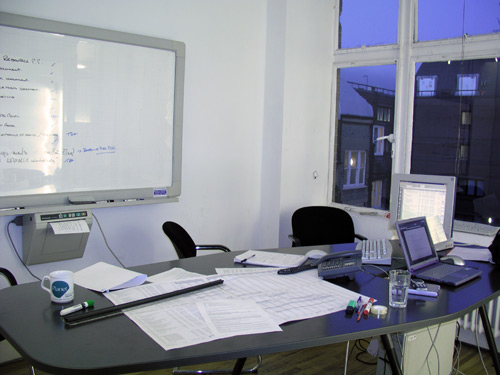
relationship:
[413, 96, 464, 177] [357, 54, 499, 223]
wall on building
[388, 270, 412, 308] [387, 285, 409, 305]
glass filled with water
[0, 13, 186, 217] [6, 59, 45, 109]
board with writing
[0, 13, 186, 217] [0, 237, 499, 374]
board behind table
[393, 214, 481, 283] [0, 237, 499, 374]
laptop on top of table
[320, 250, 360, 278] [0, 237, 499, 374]
telephone on top of table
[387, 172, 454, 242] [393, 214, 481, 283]
monitor behind laptop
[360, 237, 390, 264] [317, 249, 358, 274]
keyboard behind telephone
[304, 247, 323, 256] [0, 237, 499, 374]
mouse on table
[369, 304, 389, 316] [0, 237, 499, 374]
tape on top of table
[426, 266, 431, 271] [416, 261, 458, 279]
key on keyboard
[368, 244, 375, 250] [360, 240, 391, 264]
key on keyboard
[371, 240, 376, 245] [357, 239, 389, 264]
key on keyboard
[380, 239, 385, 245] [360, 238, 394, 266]
key on keyboard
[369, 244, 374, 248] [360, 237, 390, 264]
key on keyboard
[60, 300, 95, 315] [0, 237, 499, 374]
marker lying on top of table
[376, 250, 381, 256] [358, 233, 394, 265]
key mounted on keyboard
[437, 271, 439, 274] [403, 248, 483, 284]
key built into keyboard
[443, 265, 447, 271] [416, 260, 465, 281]
key built into keyboard